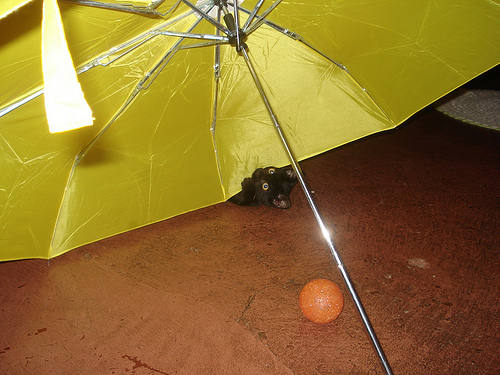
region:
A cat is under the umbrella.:
[240, 166, 296, 208]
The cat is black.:
[271, 176, 288, 193]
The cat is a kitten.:
[242, 165, 294, 208]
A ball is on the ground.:
[297, 279, 341, 324]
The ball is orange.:
[299, 276, 342, 323]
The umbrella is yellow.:
[126, 108, 196, 200]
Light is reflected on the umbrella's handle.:
[320, 226, 335, 244]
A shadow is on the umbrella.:
[73, 132, 120, 169]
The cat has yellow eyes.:
[260, 180, 270, 191]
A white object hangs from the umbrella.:
[46, 80, 82, 127]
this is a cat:
[236, 168, 313, 215]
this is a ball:
[298, 276, 346, 327]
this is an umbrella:
[14, 4, 499, 264]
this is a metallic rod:
[240, 40, 382, 374]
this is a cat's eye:
[262, 180, 270, 191]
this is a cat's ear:
[270, 190, 292, 209]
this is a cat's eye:
[265, 165, 274, 177]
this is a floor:
[6, 140, 491, 373]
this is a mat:
[436, 87, 497, 134]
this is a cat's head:
[250, 165, 302, 205]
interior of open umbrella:
[0, 3, 498, 261]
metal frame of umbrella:
[28, 2, 345, 153]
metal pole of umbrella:
[221, 7, 390, 371]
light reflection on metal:
[315, 212, 335, 252]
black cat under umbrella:
[229, 164, 299, 210]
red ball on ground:
[296, 277, 342, 323]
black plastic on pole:
[222, 14, 248, 50]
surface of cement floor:
[5, 120, 495, 369]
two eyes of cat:
[263, 166, 276, 190]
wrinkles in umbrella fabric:
[111, 53, 210, 222]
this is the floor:
[84, 283, 125, 307]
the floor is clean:
[205, 239, 265, 297]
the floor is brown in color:
[187, 242, 257, 286]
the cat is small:
[232, 163, 294, 196]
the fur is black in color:
[271, 179, 285, 186]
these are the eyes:
[257, 169, 279, 191]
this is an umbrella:
[95, 12, 377, 122]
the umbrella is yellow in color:
[122, 127, 167, 165]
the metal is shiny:
[315, 229, 339, 251]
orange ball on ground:
[293, 281, 353, 336]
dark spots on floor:
[177, 272, 306, 357]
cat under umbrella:
[224, 164, 296, 214]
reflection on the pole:
[318, 212, 343, 274]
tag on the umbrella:
[33, 0, 133, 130]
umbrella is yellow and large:
[0, 8, 445, 218]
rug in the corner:
[442, 100, 497, 130]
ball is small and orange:
[292, 272, 347, 338]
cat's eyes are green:
[253, 146, 273, 206]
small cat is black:
[224, 166, 297, 210]